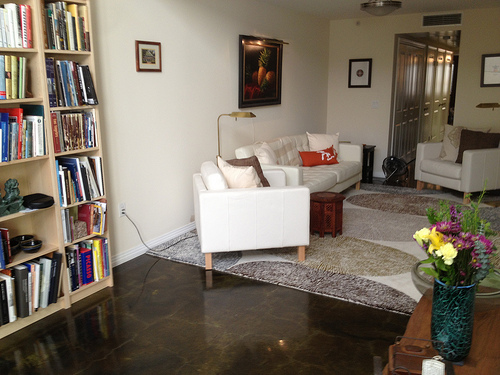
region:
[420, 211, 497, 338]
flowers are yellow in purple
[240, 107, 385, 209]
sofa is white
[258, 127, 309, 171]
blanket on the back of sofa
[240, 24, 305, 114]
light above the picture frame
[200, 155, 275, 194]
two pillows on the chair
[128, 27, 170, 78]
picture hanging on wall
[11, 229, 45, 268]
bowls on the book shelf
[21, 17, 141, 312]
books on the bookcase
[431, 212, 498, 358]
flowers in a vase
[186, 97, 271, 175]
floor lamp is between sofa and chair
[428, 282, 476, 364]
Teal and black flower vase sitting on table top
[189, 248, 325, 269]
Two pine colored solid wood chair legs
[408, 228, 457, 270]
Three silk yellow flowers in vase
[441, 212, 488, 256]
Several grape purple silk flowers with yellow centers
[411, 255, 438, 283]
Part of a large and clear class bowl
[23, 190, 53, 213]
Black vinyl CD case on book shelf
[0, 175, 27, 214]
Jade green Chinese fighting dog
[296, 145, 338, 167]
Bright red accent pillow on white sofa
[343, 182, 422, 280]
Large area rug with repeated circles in earth tones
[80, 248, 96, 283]
Blue spine of book with red letters on bookshelf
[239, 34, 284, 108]
large picture hanging on a wall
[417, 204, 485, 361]
flower in a vase on a table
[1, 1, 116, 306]
book shelves containing lots of books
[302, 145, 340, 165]
red pillow on couch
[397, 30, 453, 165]
a door left open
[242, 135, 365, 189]
a white couch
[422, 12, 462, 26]
air vent above the door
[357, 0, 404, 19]
light fixed to the ceiling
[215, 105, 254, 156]
lamp behind the couch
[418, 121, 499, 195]
recliner by the door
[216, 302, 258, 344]
part of a floor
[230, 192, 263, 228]
part of a couch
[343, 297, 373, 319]
edge of a carpet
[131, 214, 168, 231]
part of a wire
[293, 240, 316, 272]
part of a stand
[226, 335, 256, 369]
part of a floor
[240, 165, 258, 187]
edge of a cushion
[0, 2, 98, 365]
books on wooden bookshelf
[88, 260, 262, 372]
brown marble floor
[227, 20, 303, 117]
fruit still life painting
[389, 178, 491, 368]
green vase with flowers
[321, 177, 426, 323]
white carpet with brown ovals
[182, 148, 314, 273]
white chair with brown pillow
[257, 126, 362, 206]
white couch with orange pillow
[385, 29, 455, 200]
doorway with metal fan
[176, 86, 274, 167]
gold lamp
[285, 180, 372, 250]
brown circular wooden table